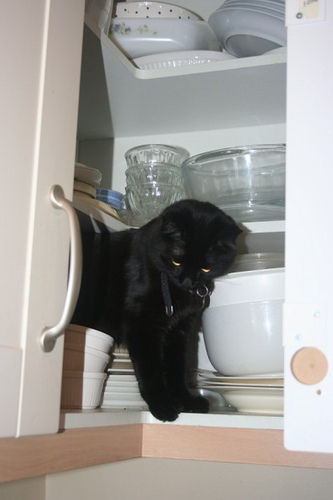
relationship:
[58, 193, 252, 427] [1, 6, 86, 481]
cat inside cupboard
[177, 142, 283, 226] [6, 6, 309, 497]
bowl inside cupboard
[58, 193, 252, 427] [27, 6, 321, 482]
cat inside cupboard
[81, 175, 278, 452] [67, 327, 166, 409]
cat over dishes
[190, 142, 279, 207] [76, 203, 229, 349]
bowl over cat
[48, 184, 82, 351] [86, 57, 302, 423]
handle of cabinet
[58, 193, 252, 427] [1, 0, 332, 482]
cat in cabinet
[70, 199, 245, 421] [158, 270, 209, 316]
black cat with collar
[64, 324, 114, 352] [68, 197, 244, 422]
bowl under a cat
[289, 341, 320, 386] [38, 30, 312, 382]
hinge of cabinet